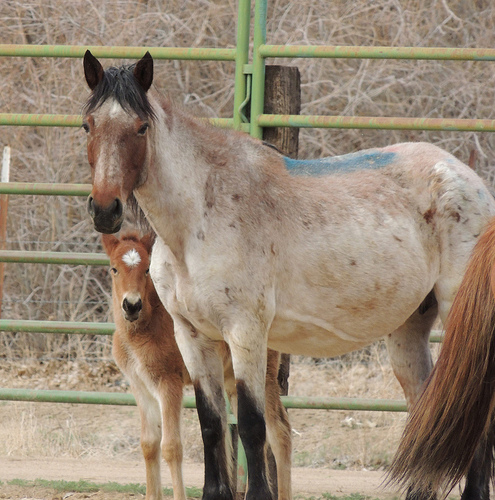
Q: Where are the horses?
A: Inside the metal fence.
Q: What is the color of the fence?
A: Green.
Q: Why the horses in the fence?
A: So they won't escape.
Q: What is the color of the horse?
A: Brown and white.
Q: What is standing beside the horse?
A: A pony.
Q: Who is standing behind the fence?
A: No one.